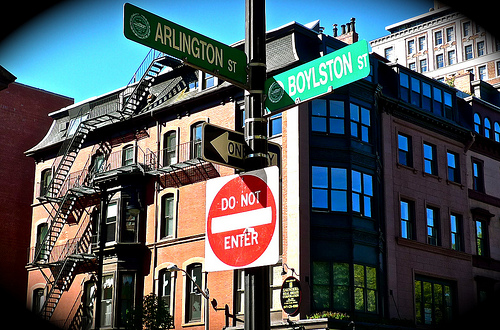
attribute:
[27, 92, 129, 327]
escape — fire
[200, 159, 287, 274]
sign — red, white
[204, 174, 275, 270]
circle — red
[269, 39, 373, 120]
sign — green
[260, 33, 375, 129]
street sign — green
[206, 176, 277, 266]
circle — red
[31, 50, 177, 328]
staircase — iron